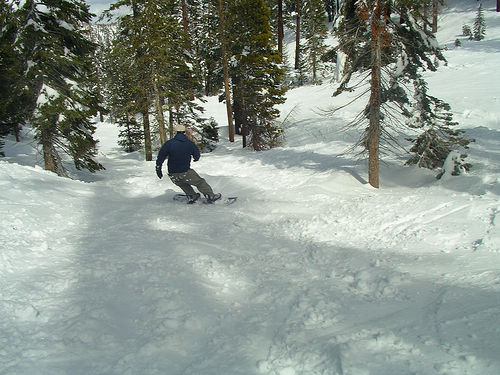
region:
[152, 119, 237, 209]
Man is on a snowboard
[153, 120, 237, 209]
Man is snowboarding down a hill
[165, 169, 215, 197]
Man is wearing pants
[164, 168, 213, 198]
Man is wearing gray pants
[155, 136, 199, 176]
Man is wearing a jacket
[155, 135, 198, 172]
Man is wearing a blue jacket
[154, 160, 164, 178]
Man is wearing gloves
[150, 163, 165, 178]
Man is wearing black gloves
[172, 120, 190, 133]
Man is wearing a hat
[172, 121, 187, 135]
Man is wearing a white hat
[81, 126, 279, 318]
This is a man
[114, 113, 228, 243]
This is a snowboarder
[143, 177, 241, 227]
This is a snowboard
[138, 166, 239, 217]
The snowboard is white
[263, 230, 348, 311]
These are footprints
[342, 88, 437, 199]
This is a tree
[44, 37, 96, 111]
This is a pine tree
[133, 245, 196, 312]
There is snow all over the ground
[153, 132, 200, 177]
The jacket is blue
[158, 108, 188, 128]
The hat is white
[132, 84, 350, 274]
a person snowboarding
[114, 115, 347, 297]
a man snowboarding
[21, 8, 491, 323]
a person snowboarding in an area with trees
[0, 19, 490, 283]
a snowy area with trees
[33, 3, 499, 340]
an area with trees and snow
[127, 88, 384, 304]
a man standing on a snowboard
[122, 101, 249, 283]
a person standing on a snowboard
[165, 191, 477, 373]
a snow covered ground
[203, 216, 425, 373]
a white snow covered ground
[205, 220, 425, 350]
a ground covered in snow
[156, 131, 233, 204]
A snowboarder in the snow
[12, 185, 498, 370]
Shadows of trees in the snow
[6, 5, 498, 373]
Snow covering the ground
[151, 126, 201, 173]
A man wearing a blue hoodie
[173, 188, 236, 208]
A black and white snowboard being riden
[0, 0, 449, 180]
Pine trees on the snowy hill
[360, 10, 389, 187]
A brown tree trunk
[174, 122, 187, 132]
A white hat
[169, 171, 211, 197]
A pair of tan pants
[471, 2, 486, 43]
A small pine tree across the hill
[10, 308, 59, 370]
SNow covering the ground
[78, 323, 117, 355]
SNow covering the ground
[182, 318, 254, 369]
SNow covering the ground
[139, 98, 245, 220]
PErson on a snowboard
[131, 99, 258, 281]
Person in a white hat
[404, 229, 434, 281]
SNow covering the ground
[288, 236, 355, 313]
SNow covering the ground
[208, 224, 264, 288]
SNow covering the ground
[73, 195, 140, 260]
SNow covering the ground